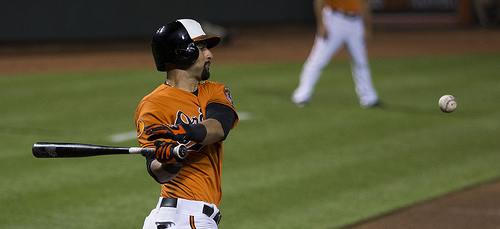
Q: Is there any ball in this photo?
A: Yes, there is a ball.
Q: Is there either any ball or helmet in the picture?
A: Yes, there is a ball.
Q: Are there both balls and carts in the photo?
A: No, there is a ball but no carts.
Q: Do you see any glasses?
A: No, there are no glasses.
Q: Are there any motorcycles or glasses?
A: No, there are no glasses or motorcycles.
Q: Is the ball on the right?
A: Yes, the ball is on the right of the image.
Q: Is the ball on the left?
A: No, the ball is on the right of the image.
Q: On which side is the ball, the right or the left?
A: The ball is on the right of the image.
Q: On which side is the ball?
A: The ball is on the right of the image.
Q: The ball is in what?
A: The ball is in the air.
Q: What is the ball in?
A: The ball is in the air.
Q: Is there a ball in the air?
A: Yes, there is a ball in the air.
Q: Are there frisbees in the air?
A: No, there is a ball in the air.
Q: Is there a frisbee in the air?
A: No, there is a ball in the air.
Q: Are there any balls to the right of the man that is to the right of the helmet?
A: Yes, there is a ball to the right of the man.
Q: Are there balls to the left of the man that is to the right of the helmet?
A: No, the ball is to the right of the man.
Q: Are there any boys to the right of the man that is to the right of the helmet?
A: No, there is a ball to the right of the man.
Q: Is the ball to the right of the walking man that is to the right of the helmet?
A: Yes, the ball is to the right of the man.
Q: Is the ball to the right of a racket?
A: No, the ball is to the right of the man.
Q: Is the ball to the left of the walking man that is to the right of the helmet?
A: No, the ball is to the right of the man.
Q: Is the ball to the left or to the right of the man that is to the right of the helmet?
A: The ball is to the right of the man.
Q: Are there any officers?
A: No, there are no officers.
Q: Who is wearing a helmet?
A: The man is wearing a helmet.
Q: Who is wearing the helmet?
A: The man is wearing a helmet.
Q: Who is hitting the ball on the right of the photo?
A: The man is hitting the ball.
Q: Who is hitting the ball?
A: The man is hitting the ball.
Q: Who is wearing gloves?
A: The man is wearing gloves.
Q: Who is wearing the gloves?
A: The man is wearing gloves.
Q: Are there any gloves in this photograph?
A: Yes, there are gloves.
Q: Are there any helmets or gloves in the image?
A: Yes, there are gloves.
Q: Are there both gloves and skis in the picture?
A: No, there are gloves but no skis.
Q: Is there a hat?
A: No, there are no hats.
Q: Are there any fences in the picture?
A: No, there are no fences.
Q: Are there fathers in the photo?
A: No, there are no fathers.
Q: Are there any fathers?
A: No, there are no fathers.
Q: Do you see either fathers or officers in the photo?
A: No, there are no fathers or officers.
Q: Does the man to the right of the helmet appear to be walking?
A: Yes, the man is walking.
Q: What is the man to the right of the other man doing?
A: The man is walking.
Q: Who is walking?
A: The man is walking.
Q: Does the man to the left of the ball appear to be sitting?
A: No, the man is walking.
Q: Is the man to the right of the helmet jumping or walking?
A: The man is walking.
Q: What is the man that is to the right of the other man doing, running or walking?
A: The man is walking.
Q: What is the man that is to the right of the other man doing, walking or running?
A: The man is walking.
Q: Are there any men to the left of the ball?
A: Yes, there is a man to the left of the ball.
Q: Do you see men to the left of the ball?
A: Yes, there is a man to the left of the ball.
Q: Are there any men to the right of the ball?
A: No, the man is to the left of the ball.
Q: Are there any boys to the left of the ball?
A: No, there is a man to the left of the ball.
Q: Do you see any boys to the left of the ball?
A: No, there is a man to the left of the ball.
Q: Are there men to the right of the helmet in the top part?
A: Yes, there is a man to the right of the helmet.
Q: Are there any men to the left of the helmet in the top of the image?
A: No, the man is to the right of the helmet.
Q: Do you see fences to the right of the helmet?
A: No, there is a man to the right of the helmet.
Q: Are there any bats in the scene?
A: Yes, there is a bat.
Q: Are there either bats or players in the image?
A: Yes, there is a bat.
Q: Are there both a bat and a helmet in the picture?
A: Yes, there are both a bat and a helmet.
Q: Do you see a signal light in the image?
A: No, there are no traffic lights.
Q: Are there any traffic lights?
A: No, there are no traffic lights.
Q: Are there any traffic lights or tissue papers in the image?
A: No, there are no traffic lights or tissue papers.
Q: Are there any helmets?
A: Yes, there is a helmet.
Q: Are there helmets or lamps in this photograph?
A: Yes, there is a helmet.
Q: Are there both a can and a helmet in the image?
A: No, there is a helmet but no cans.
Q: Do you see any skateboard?
A: No, there are no skateboards.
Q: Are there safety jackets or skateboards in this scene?
A: No, there are no skateboards or safety jackets.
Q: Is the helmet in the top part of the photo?
A: Yes, the helmet is in the top of the image.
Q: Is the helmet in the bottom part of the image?
A: No, the helmet is in the top of the image.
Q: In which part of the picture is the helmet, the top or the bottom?
A: The helmet is in the top of the image.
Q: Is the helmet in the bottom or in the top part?
A: The helmet is in the top of the image.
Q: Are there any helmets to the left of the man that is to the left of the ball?
A: Yes, there is a helmet to the left of the man.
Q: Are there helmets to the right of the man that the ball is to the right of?
A: No, the helmet is to the left of the man.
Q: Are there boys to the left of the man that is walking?
A: No, there is a helmet to the left of the man.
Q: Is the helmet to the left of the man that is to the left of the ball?
A: Yes, the helmet is to the left of the man.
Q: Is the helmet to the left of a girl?
A: No, the helmet is to the left of the man.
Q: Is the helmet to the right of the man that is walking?
A: No, the helmet is to the left of the man.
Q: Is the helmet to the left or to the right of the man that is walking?
A: The helmet is to the left of the man.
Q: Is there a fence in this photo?
A: No, there are no fences.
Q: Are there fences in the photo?
A: No, there are no fences.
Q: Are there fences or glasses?
A: No, there are no fences or glasses.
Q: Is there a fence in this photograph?
A: No, there are no fences.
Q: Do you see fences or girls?
A: No, there are no fences or girls.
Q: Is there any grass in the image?
A: Yes, there is grass.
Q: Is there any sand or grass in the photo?
A: Yes, there is grass.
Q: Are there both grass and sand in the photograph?
A: No, there is grass but no sand.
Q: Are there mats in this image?
A: No, there are no mats.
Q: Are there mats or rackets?
A: No, there are no mats or rackets.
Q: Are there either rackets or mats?
A: No, there are no mats or rackets.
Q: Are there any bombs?
A: No, there are no bombs.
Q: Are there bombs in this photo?
A: No, there are no bombs.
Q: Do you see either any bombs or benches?
A: No, there are no bombs or benches.